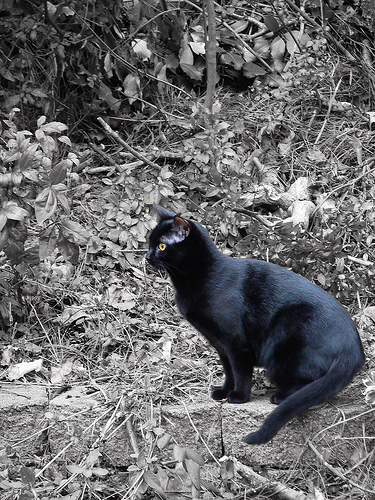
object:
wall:
[2, 419, 374, 463]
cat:
[138, 200, 368, 450]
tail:
[245, 385, 348, 445]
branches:
[116, 396, 142, 460]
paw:
[226, 387, 248, 406]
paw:
[210, 382, 226, 399]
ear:
[154, 202, 170, 222]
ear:
[166, 212, 189, 239]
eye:
[154, 240, 167, 252]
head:
[141, 206, 208, 274]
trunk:
[200, 1, 224, 110]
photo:
[1, 1, 371, 498]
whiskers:
[170, 259, 178, 271]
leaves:
[119, 215, 134, 230]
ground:
[1, 104, 374, 389]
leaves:
[113, 297, 138, 311]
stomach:
[255, 321, 291, 371]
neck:
[165, 251, 225, 288]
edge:
[4, 402, 374, 415]